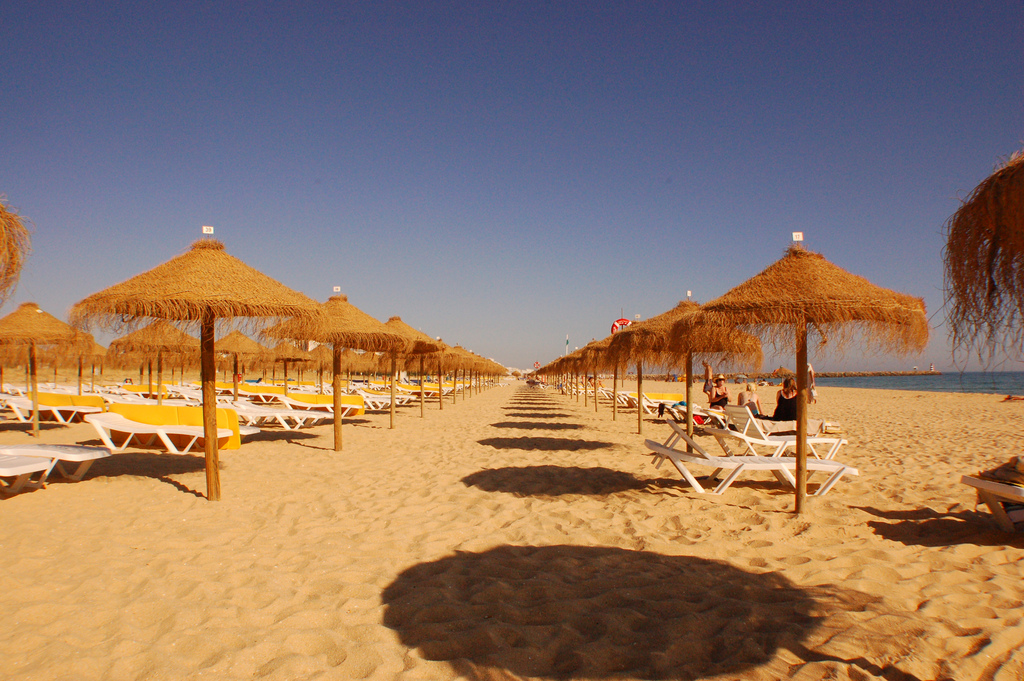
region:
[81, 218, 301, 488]
Tall straw umbrella on beach.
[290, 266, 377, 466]
Tall straw umbrella on beach.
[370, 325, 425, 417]
Tall straw umbrella on beach.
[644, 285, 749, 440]
Tall straw umbrella on beach.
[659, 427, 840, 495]
White lounge chair on beach.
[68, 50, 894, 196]
Sky is blue and clear.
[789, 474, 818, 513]
pole on the beach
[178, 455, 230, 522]
pole on the beach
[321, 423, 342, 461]
pole on the beach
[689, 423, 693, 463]
pole on the beach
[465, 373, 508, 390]
pole on the beach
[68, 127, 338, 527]
Straw umbrella on the beach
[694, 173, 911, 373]
White top on the straw umbrella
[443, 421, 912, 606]
A shadow is on the sand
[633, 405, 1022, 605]
A white chair is on the beach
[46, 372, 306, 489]
A yellow towel is on the white chair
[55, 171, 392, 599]
The umbrella is made of straw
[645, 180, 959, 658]
The umbrella is brown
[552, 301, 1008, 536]
The beach is near the water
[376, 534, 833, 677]
circular shadow in the front of the picture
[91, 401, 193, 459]
white lounge chair sitting on the beach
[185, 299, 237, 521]
brown pole in the middle of an umbrella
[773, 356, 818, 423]
person in black swimsuit sitting on the beach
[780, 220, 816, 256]
small white flag on top of beach umbrella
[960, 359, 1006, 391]
crystal blue water in the distance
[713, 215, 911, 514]
tall brown grassy beach umbrella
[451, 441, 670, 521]
second round shadow in center of photo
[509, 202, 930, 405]
straw umbrella's all in a line on a beach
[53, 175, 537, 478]
left line of umbrella's in a row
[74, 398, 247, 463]
white lounge chair on the beach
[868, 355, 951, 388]
land sitting out in the water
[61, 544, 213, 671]
Footprints in the sand on the beach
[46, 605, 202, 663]
Footprints in the sand on the beach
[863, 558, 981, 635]
Footprints in the sand on the beach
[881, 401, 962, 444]
Footprints in the sand on the beach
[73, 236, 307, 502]
a large open umbrella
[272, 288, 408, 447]
a large open umbrella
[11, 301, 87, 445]
a large open umbrella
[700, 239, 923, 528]
a large open umbrella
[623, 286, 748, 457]
a large open umbrella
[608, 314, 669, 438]
a large open umbrella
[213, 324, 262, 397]
a large open umbrella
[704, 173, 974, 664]
a straw beach umbrella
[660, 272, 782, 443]
a straw beach umbrella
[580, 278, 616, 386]
a straw beach umbrella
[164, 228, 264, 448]
a straw beach umbrella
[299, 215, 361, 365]
a straw beach umbrella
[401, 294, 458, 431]
a straw beach umbrella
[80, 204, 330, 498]
a large open umbrella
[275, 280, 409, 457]
a large open umbrella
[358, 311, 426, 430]
a large open umbrella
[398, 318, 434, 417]
a large open umbrella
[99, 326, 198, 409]
a large open umbrella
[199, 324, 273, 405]
a large open umbrella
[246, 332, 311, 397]
a large open umbrella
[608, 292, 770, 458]
a large open umbrella